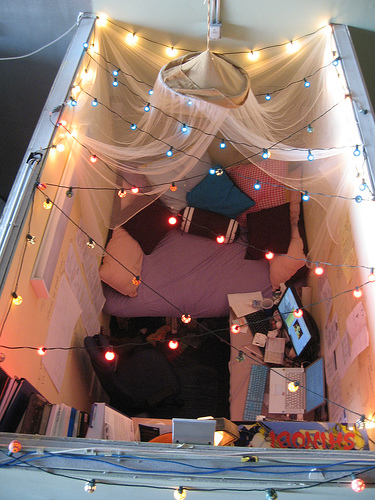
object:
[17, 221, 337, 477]
room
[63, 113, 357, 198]
netting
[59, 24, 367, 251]
mosquito netting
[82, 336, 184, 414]
chair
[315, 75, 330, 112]
ground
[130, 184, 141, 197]
light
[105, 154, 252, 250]
cord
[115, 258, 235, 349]
cord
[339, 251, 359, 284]
paper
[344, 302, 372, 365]
paper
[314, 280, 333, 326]
paper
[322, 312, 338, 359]
paper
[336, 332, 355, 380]
paper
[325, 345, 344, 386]
paper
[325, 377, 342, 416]
paper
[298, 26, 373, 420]
wall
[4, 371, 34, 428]
helmet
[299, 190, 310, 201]
light bulb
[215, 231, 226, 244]
red light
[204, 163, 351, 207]
cord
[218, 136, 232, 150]
blue bulb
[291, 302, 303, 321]
lightbulb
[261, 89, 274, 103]
light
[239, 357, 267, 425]
television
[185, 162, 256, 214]
blue pillow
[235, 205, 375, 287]
cord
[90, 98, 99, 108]
light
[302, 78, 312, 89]
light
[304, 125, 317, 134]
light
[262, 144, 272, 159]
light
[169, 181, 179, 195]
light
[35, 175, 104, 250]
cord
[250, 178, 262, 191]
blue light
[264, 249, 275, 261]
light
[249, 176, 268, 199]
light bulb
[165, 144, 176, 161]
light bulb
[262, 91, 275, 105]
light bulb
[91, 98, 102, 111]
light bulb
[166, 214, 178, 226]
light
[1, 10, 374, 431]
string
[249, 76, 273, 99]
ground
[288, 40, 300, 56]
light bulb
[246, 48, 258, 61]
light bulb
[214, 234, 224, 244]
light bulb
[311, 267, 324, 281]
light bulb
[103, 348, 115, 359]
light bulb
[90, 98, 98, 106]
lightbulb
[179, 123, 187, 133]
lightbulb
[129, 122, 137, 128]
lightbulb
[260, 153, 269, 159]
lightbulb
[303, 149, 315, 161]
lightbulb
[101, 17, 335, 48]
cord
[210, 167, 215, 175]
light bulb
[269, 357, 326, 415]
laptop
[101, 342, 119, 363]
light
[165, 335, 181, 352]
light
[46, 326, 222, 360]
cord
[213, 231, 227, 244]
light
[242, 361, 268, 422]
keyboard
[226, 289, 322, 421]
desk